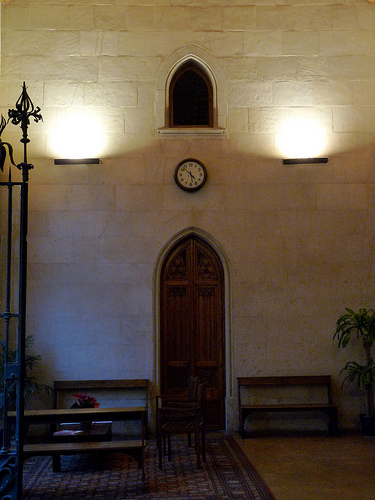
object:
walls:
[0, 1, 375, 431]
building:
[1, 1, 374, 498]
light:
[46, 94, 111, 164]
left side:
[0, 1, 200, 499]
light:
[270, 114, 331, 161]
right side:
[197, 3, 375, 497]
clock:
[172, 157, 210, 193]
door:
[157, 230, 229, 432]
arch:
[152, 223, 227, 260]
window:
[164, 53, 221, 130]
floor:
[233, 428, 375, 498]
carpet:
[0, 417, 275, 500]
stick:
[8, 76, 44, 500]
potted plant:
[329, 306, 375, 441]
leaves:
[332, 304, 375, 396]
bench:
[236, 376, 335, 437]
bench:
[51, 375, 148, 442]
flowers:
[66, 391, 101, 408]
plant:
[70, 391, 102, 430]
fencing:
[1, 80, 44, 500]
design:
[1, 83, 48, 180]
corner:
[328, 2, 375, 499]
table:
[49, 409, 115, 458]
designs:
[14, 442, 238, 499]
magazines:
[58, 418, 111, 436]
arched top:
[165, 55, 217, 90]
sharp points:
[5, 77, 44, 138]